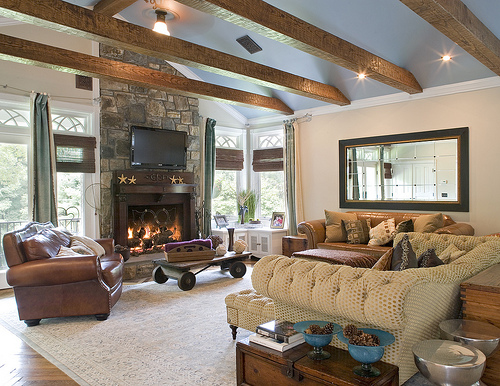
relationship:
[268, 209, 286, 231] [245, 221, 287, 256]
framed picture on a table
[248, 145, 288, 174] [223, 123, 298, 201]
shade hanging on a window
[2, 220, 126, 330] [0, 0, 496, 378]
chair in living room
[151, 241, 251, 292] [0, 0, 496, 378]
item in living room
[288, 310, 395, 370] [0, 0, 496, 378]
items in living room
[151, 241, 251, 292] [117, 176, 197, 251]
item in front of fireplace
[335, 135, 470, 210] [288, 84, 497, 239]
items/living room hanging on wall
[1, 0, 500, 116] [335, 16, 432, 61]
beam on ceiling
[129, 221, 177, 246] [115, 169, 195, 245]
fire lit in fireplace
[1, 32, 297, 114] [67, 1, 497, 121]
beam across ceiling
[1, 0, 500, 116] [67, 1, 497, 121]
beam across ceiling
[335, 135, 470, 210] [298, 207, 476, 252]
items/living room over chairs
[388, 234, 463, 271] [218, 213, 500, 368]
pillows are on chair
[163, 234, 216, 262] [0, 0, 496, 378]
items in living room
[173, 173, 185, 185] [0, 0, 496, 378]
items in living room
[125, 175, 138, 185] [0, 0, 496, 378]
items in living room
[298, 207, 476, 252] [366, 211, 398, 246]
chairs with pillows